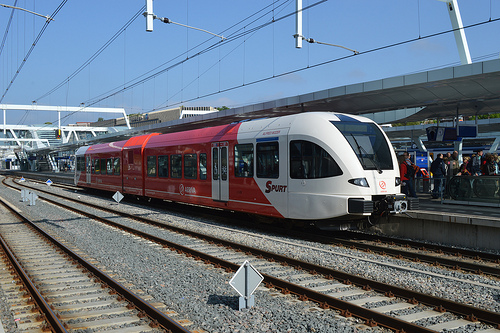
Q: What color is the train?
A: Red, white.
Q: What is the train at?
A: Train station.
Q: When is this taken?
A: Daytime.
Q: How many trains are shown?
A: 1.